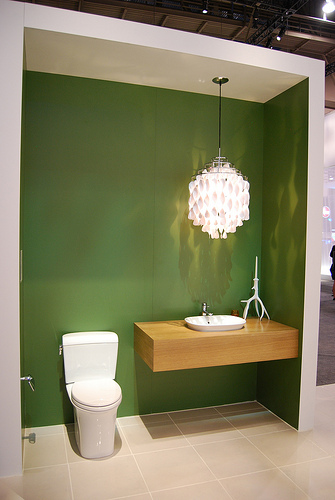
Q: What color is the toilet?
A: White.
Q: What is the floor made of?
A: Tiles.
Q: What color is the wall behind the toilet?
A: Green.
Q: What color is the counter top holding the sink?
A: Brown.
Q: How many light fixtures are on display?
A: One.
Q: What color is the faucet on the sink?
A: Silver.